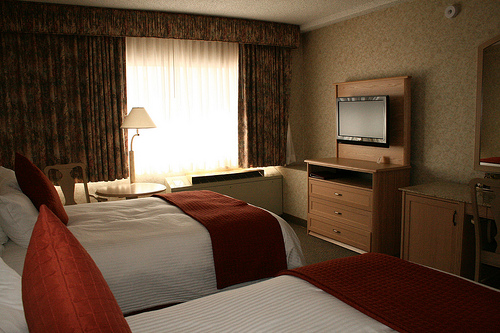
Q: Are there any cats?
A: No, there are no cats.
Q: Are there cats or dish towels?
A: No, there are no cats or dish towels.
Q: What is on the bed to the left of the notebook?
A: The comforter is on the bed.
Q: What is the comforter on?
A: The comforter is on the bed.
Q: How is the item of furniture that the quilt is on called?
A: The piece of furniture is a bed.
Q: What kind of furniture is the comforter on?
A: The quilt is on the bed.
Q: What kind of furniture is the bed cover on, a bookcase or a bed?
A: The bed cover is on a bed.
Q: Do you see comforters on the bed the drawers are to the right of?
A: Yes, there is a comforter on the bed.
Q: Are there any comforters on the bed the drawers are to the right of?
A: Yes, there is a comforter on the bed.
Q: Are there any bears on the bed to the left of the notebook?
A: No, there is a comforter on the bed.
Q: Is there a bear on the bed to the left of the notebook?
A: No, there is a comforter on the bed.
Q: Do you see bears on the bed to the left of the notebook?
A: No, there is a comforter on the bed.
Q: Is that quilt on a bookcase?
A: No, the quilt is on a bed.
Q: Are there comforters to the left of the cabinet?
A: Yes, there is a comforter to the left of the cabinet.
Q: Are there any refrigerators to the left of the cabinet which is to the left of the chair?
A: No, there is a comforter to the left of the cabinet.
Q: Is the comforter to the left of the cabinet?
A: Yes, the comforter is to the left of the cabinet.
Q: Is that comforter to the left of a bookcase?
A: No, the comforter is to the left of the cabinet.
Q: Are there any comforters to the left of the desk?
A: Yes, there is a comforter to the left of the desk.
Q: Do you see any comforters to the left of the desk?
A: Yes, there is a comforter to the left of the desk.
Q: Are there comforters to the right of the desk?
A: No, the comforter is to the left of the desk.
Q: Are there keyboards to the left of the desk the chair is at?
A: No, there is a comforter to the left of the desk.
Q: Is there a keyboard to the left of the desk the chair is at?
A: No, there is a comforter to the left of the desk.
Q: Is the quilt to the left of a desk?
A: Yes, the quilt is to the left of a desk.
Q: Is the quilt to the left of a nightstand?
A: No, the quilt is to the left of a desk.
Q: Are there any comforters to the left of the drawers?
A: Yes, there is a comforter to the left of the drawers.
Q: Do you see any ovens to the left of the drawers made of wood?
A: No, there is a comforter to the left of the drawers.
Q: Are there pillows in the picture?
A: Yes, there is a pillow.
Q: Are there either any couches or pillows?
A: Yes, there is a pillow.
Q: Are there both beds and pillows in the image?
A: Yes, there are both a pillow and a bed.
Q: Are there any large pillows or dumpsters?
A: Yes, there is a large pillow.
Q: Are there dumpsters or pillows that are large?
A: Yes, the pillow is large.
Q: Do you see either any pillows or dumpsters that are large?
A: Yes, the pillow is large.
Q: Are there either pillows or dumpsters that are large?
A: Yes, the pillow is large.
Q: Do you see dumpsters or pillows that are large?
A: Yes, the pillow is large.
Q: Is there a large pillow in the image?
A: Yes, there is a large pillow.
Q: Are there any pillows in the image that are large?
A: Yes, there is a pillow that is large.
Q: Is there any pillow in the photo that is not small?
A: Yes, there is a large pillow.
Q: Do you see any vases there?
A: No, there are no vases.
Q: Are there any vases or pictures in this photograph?
A: No, there are no vases or pictures.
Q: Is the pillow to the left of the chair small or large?
A: The pillow is large.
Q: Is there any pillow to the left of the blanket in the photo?
A: Yes, there is a pillow to the left of the blanket.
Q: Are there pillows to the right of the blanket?
A: No, the pillow is to the left of the blanket.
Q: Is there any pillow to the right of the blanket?
A: No, the pillow is to the left of the blanket.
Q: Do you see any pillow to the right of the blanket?
A: No, the pillow is to the left of the blanket.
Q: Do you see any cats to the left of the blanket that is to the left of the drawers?
A: No, there is a pillow to the left of the blanket.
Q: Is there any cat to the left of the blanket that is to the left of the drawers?
A: No, there is a pillow to the left of the blanket.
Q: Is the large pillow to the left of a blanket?
A: Yes, the pillow is to the left of a blanket.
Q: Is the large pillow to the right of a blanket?
A: No, the pillow is to the left of a blanket.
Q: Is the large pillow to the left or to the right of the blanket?
A: The pillow is to the left of the blanket.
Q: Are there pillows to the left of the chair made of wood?
A: Yes, there is a pillow to the left of the chair.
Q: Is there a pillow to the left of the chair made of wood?
A: Yes, there is a pillow to the left of the chair.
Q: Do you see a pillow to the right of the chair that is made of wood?
A: No, the pillow is to the left of the chair.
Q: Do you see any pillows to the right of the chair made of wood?
A: No, the pillow is to the left of the chair.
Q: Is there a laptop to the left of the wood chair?
A: No, there is a pillow to the left of the chair.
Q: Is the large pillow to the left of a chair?
A: Yes, the pillow is to the left of a chair.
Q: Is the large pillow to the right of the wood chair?
A: No, the pillow is to the left of the chair.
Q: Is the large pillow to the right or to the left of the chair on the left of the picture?
A: The pillow is to the left of the chair.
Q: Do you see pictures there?
A: No, there are no pictures.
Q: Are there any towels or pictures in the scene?
A: No, there are no pictures or towels.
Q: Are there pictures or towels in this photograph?
A: No, there are no pictures or towels.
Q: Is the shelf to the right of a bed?
A: Yes, the shelf is to the right of a bed.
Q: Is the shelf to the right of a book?
A: No, the shelf is to the right of a bed.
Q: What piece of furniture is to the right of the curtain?
A: The piece of furniture is a shelf.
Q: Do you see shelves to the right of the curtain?
A: Yes, there is a shelf to the right of the curtain.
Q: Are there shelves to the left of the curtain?
A: No, the shelf is to the right of the curtain.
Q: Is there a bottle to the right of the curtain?
A: No, there is a shelf to the right of the curtain.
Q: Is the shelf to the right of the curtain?
A: Yes, the shelf is to the right of the curtain.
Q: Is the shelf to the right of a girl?
A: No, the shelf is to the right of the curtain.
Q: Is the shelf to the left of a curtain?
A: No, the shelf is to the right of a curtain.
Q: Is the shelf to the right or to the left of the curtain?
A: The shelf is to the right of the curtain.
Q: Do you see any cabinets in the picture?
A: Yes, there is a cabinet.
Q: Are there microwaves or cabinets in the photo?
A: Yes, there is a cabinet.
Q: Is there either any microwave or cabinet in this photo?
A: Yes, there is a cabinet.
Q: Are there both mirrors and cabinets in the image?
A: Yes, there are both a cabinet and a mirror.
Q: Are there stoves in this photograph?
A: No, there are no stoves.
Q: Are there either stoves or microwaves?
A: No, there are no stoves or microwaves.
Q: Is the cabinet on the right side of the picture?
A: Yes, the cabinet is on the right of the image.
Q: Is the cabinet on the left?
A: No, the cabinet is on the right of the image.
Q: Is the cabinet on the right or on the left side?
A: The cabinet is on the right of the image.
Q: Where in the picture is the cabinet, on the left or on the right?
A: The cabinet is on the right of the image.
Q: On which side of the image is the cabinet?
A: The cabinet is on the right of the image.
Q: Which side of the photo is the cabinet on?
A: The cabinet is on the right of the image.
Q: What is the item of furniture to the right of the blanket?
A: The piece of furniture is a cabinet.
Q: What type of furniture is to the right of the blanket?
A: The piece of furniture is a cabinet.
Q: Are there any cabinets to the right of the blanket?
A: Yes, there is a cabinet to the right of the blanket.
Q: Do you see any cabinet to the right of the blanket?
A: Yes, there is a cabinet to the right of the blanket.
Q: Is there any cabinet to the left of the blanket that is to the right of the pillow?
A: No, the cabinet is to the right of the blanket.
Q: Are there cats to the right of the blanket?
A: No, there is a cabinet to the right of the blanket.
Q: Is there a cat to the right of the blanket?
A: No, there is a cabinet to the right of the blanket.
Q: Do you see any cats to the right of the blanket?
A: No, there is a cabinet to the right of the blanket.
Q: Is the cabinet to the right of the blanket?
A: Yes, the cabinet is to the right of the blanket.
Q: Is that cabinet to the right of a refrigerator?
A: No, the cabinet is to the right of the blanket.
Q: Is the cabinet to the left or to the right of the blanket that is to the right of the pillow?
A: The cabinet is to the right of the blanket.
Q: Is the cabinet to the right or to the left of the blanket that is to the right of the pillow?
A: The cabinet is to the right of the blanket.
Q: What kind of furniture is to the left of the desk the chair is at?
A: The piece of furniture is a cabinet.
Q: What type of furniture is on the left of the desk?
A: The piece of furniture is a cabinet.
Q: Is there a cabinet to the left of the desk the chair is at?
A: Yes, there is a cabinet to the left of the desk.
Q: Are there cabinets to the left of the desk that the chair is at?
A: Yes, there is a cabinet to the left of the desk.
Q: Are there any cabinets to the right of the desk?
A: No, the cabinet is to the left of the desk.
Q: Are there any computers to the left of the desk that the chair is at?
A: No, there is a cabinet to the left of the desk.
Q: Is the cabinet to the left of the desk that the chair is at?
A: Yes, the cabinet is to the left of the desk.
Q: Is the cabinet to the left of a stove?
A: No, the cabinet is to the left of the desk.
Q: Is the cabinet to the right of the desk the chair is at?
A: No, the cabinet is to the left of the desk.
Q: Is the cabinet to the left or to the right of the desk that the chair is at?
A: The cabinet is to the left of the desk.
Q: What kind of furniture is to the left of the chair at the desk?
A: The piece of furniture is a cabinet.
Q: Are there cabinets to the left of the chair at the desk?
A: Yes, there is a cabinet to the left of the chair.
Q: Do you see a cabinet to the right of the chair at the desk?
A: No, the cabinet is to the left of the chair.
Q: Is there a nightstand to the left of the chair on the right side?
A: No, there is a cabinet to the left of the chair.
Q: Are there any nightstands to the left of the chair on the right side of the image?
A: No, there is a cabinet to the left of the chair.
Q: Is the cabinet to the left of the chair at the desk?
A: Yes, the cabinet is to the left of the chair.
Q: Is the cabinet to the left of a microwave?
A: No, the cabinet is to the left of the chair.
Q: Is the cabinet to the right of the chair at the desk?
A: No, the cabinet is to the left of the chair.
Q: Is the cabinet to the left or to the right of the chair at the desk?
A: The cabinet is to the left of the chair.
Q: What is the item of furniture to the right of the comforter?
A: The piece of furniture is a cabinet.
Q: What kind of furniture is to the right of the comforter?
A: The piece of furniture is a cabinet.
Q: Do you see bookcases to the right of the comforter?
A: No, there is a cabinet to the right of the comforter.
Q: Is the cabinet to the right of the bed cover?
A: Yes, the cabinet is to the right of the bed cover.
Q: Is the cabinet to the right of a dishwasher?
A: No, the cabinet is to the right of the bed cover.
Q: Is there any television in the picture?
A: Yes, there is a television.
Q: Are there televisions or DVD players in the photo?
A: Yes, there is a television.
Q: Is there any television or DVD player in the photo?
A: Yes, there is a television.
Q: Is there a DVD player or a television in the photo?
A: Yes, there is a television.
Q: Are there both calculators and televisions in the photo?
A: No, there is a television but no calculators.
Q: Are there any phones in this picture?
A: No, there are no phones.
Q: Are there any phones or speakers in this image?
A: No, there are no phones or speakers.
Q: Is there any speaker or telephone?
A: No, there are no phones or speakers.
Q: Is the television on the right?
A: Yes, the television is on the right of the image.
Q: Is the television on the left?
A: No, the television is on the right of the image.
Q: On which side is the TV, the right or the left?
A: The TV is on the right of the image.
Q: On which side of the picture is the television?
A: The television is on the right of the image.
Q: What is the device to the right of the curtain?
A: The device is a television.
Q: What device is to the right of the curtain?
A: The device is a television.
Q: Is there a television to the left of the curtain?
A: No, the television is to the right of the curtain.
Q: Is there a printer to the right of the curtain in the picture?
A: No, there is a television to the right of the curtain.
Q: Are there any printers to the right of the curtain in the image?
A: No, there is a television to the right of the curtain.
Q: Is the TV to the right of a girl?
A: No, the TV is to the right of the curtain.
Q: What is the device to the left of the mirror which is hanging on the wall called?
A: The device is a television.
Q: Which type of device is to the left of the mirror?
A: The device is a television.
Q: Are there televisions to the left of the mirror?
A: Yes, there is a television to the left of the mirror.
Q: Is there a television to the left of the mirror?
A: Yes, there is a television to the left of the mirror.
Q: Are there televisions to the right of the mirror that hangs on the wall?
A: No, the television is to the left of the mirror.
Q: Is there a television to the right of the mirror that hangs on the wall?
A: No, the television is to the left of the mirror.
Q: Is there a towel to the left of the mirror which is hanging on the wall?
A: No, there is a television to the left of the mirror.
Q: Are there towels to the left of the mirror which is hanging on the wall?
A: No, there is a television to the left of the mirror.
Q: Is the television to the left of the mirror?
A: Yes, the television is to the left of the mirror.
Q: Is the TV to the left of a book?
A: No, the TV is to the left of the mirror.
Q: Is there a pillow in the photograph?
A: Yes, there is a pillow.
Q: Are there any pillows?
A: Yes, there is a pillow.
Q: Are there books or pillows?
A: Yes, there is a pillow.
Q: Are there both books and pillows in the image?
A: No, there is a pillow but no books.